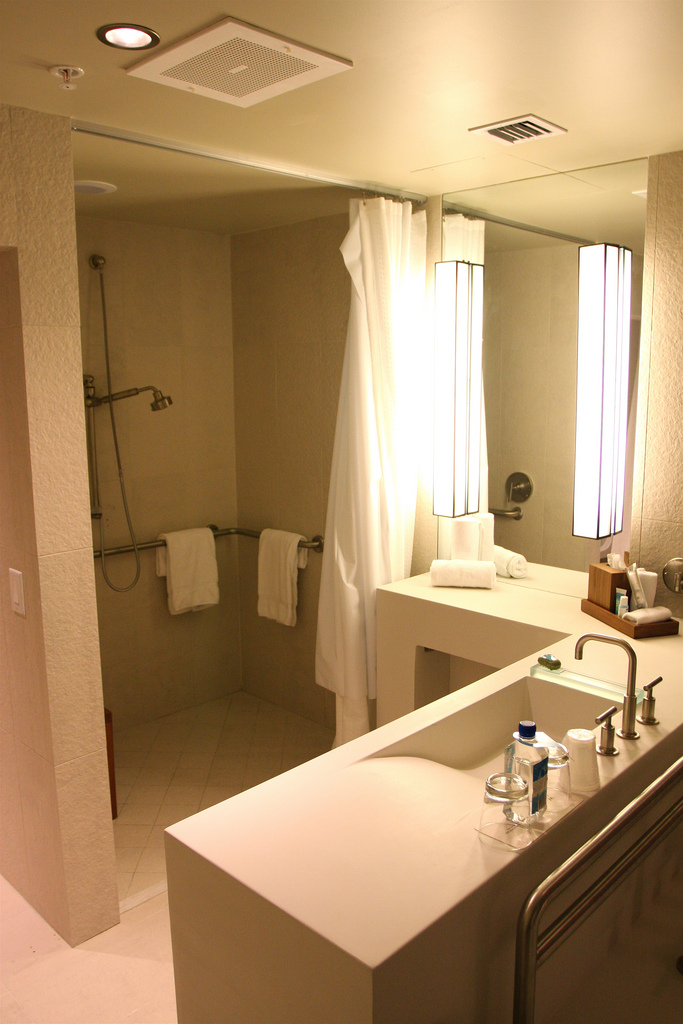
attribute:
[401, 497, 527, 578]
towel — rolled up, standing up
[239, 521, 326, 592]
towel — silver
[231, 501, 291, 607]
towel — rolled up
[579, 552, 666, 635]
tissue box — brown, wood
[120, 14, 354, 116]
speaker — rectangular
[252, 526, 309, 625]
towel — white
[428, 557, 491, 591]
towel — white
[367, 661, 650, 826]
sink — white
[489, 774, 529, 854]
glass — clear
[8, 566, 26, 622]
switch — white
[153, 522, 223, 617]
towel — white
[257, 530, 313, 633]
towel — white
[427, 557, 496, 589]
towel — white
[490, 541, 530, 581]
towel — white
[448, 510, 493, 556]
towel — white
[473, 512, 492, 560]
towel — white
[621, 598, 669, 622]
towel — white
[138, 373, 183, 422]
head — shower